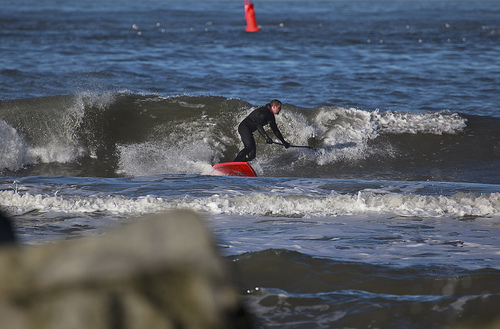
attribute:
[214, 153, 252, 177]
surfboard — red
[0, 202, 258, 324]
rock boulder — blurry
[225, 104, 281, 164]
surfer suit — black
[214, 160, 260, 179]
wakeboard — red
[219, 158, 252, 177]
wakeboard — red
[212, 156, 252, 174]
wakeboard — red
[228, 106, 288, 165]
wetsuit — black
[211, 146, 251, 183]
surfboard — red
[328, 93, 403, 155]
cap — white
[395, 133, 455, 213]
wave — crashing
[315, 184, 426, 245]
foam — white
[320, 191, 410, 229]
seafoam — white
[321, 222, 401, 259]
surface — water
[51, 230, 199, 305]
rock — blurry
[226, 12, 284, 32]
bouy — red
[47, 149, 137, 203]
wave — crashing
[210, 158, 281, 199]
surfboard — red, long